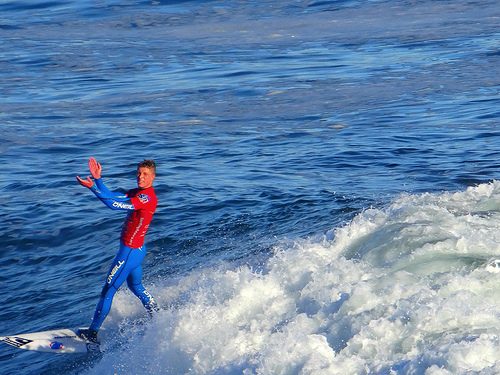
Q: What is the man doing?
A: Surfing.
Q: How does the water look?
A: Blue.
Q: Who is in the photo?
A: A man.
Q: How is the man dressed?
A: Red and blue outfit.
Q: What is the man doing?
A: Surfing.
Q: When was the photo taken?
A: During surfing.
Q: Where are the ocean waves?
A: Behind man.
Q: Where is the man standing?
A: On surfboard.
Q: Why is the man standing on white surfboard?
A: To surf.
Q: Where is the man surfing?
A: In ocean.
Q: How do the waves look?
A: White.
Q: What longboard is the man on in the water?
A: Surfboard.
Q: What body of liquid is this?
A: Water.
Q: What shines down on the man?
A: Sun.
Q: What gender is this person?
A: Male.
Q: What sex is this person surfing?
A: Male.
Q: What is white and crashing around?
A: Waves.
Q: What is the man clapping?
A: Hands.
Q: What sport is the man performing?
A: Surfing.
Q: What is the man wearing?
A: Wetsuit.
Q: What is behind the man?
A: A crashing wave.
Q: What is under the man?
A: A Surfboard.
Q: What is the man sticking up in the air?
A: His hands.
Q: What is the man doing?
A: Surfing.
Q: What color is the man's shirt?
A: Red.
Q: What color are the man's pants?
A: Blue.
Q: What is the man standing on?
A: A surf board.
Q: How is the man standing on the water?
A: Using a surfboard.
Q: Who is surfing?
A: A man.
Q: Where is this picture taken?
A: On water.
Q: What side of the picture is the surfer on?
A: Left.